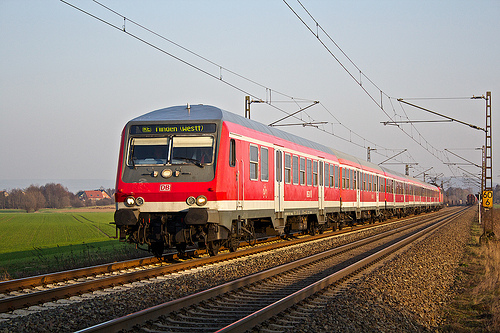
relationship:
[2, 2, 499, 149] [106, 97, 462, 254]
sky above train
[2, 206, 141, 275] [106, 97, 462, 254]
field behind train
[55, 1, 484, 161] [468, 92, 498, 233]
wires are attached to pole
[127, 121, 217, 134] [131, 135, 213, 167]
information on top of windshield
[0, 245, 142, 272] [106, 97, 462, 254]
weeds are beside train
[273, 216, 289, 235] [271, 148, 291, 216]
step below doors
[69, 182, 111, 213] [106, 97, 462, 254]
house behind train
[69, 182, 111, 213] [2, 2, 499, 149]
house below sky